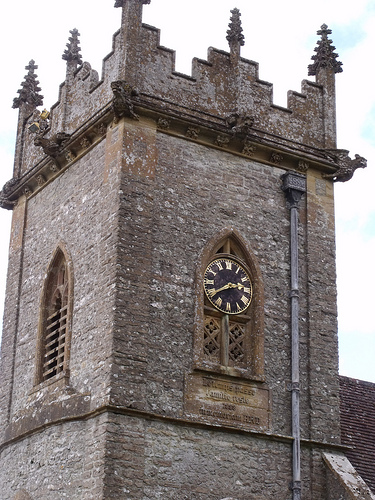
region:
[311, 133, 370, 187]
this statue in on the far right of the building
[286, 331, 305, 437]
the pole is silver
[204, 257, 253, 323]
the clock is black and gold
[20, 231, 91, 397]
this window has bars on it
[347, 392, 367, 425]
the roof is reddish brown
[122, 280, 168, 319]
this is a very old brick building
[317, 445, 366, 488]
this piece has white flaky paint on it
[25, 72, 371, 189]
the four statues on the building are old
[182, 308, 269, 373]
this window is decortive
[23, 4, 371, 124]
the top has four decorative pieces on it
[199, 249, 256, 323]
big old analog clock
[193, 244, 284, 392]
a clock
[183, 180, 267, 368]
a clock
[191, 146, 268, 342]
a clock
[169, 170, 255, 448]
a clock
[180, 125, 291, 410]
a clock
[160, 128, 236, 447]
a clock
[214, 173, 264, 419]
a clock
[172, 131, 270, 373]
a clock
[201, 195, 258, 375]
a clock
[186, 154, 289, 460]
a clock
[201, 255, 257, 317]
the round face of a clock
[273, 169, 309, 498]
a gray pipe on the building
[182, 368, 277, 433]
a plaque under the clock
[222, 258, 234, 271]
a number on the clock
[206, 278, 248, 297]
the hands of the clock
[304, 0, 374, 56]
a patch of blue sky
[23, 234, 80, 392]
a window on the tower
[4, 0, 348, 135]
the top of the tower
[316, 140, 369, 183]
a gargoyle on the building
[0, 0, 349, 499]
a large clock tower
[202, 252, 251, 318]
old roman analog clock